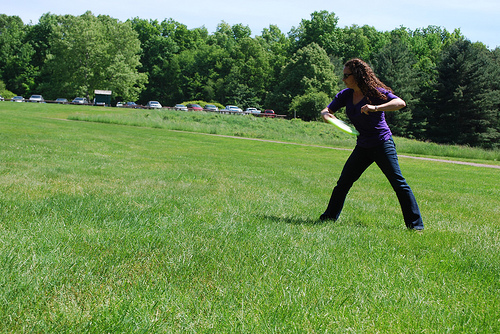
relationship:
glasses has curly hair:
[343, 72, 354, 78] [343, 58, 395, 105]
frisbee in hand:
[318, 108, 353, 137] [359, 100, 376, 115]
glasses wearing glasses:
[343, 72, 354, 78] [342, 72, 354, 78]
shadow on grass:
[256, 210, 331, 229] [0, 122, 322, 332]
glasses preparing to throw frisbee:
[343, 72, 354, 78] [317, 105, 363, 139]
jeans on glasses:
[319, 133, 423, 231] [343, 72, 354, 78]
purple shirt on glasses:
[325, 86, 398, 142] [343, 72, 354, 78]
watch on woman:
[374, 104, 379, 112] [310, 55, 428, 232]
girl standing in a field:
[314, 56, 431, 236] [0, 95, 498, 331]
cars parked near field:
[1, 94, 282, 117] [0, 95, 498, 331]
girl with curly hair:
[314, 56, 431, 236] [343, 58, 395, 105]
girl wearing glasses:
[314, 56, 431, 236] [343, 72, 354, 78]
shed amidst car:
[88, 85, 113, 110] [28, 84, 44, 101]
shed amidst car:
[88, 85, 113, 110] [121, 93, 139, 103]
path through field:
[205, 130, 499, 170] [0, 95, 498, 331]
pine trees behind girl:
[381, 38, 496, 140] [324, 60, 422, 231]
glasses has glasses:
[343, 72, 354, 78] [342, 69, 356, 79]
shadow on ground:
[256, 194, 333, 246] [206, 158, 416, 305]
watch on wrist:
[373, 103, 382, 113] [373, 100, 385, 114]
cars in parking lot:
[1, 87, 285, 120] [6, 96, 269, 112]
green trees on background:
[61, 12, 291, 101] [2, 29, 498, 119]